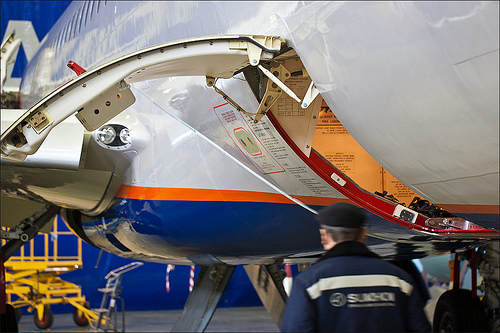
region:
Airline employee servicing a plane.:
[277, 195, 434, 330]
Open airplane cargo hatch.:
[271, 32, 434, 242]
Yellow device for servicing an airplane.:
[11, 234, 96, 328]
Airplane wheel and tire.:
[427, 288, 484, 330]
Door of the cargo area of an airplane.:
[0, 33, 322, 164]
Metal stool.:
[91, 262, 140, 331]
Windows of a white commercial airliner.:
[36, 0, 141, 57]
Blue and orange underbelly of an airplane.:
[126, 188, 308, 265]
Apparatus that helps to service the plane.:
[174, 250, 290, 330]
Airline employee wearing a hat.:
[281, 201, 424, 331]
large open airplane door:
[37, 53, 452, 210]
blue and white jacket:
[299, 248, 429, 330]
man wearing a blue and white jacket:
[311, 202, 410, 330]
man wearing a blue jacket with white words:
[311, 198, 430, 328]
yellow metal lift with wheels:
[12, 227, 153, 324]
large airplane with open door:
[13, 10, 485, 211]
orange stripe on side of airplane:
[98, 176, 498, 212]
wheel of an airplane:
[435, 287, 495, 327]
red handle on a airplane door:
[51, 56, 123, 101]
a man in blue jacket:
[284, 199, 429, 331]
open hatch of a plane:
[242, 52, 477, 237]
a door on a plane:
[0, 34, 282, 164]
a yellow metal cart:
[4, 212, 111, 330]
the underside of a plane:
[15, 2, 495, 269]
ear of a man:
[319, 227, 327, 244]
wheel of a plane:
[430, 289, 493, 331]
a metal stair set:
[95, 260, 145, 330]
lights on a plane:
[94, 123, 129, 148]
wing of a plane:
[0, 109, 129, 215]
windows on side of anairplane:
[42, 0, 119, 55]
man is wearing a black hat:
[314, 199, 369, 229]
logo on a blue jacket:
[325, 290, 397, 307]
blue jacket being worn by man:
[278, 241, 434, 331]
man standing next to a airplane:
[277, 201, 434, 331]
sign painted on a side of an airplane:
[210, 99, 285, 177]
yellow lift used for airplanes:
[2, 176, 119, 330]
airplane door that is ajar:
[0, 31, 285, 167]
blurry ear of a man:
[317, 226, 327, 246]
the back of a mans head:
[316, 199, 368, 255]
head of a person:
[313, 202, 371, 255]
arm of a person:
[290, 272, 317, 321]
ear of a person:
[309, 214, 324, 245]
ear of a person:
[352, 227, 374, 250]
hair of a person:
[326, 225, 365, 243]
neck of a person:
[320, 245, 380, 267]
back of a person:
[317, 256, 412, 321]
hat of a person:
[298, 197, 371, 239]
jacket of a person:
[275, 248, 420, 325]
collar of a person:
[313, 237, 375, 270]